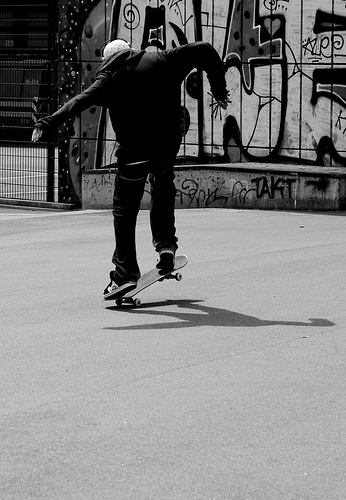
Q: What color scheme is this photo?
A: Grayscale.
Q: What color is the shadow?
A: Black.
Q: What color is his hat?
A: White.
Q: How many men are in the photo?
A: One.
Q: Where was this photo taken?
A: At a skate park.